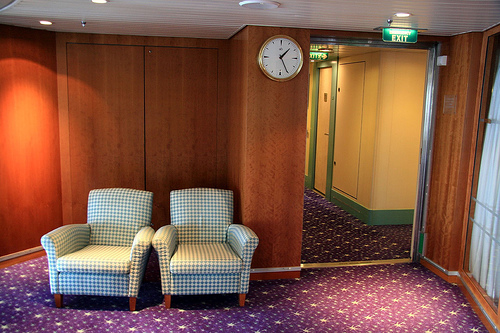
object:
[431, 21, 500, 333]
door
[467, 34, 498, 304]
glass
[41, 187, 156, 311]
chair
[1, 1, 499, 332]
room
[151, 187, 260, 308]
chair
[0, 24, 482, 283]
walls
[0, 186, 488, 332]
floor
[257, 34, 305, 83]
clock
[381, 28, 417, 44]
sign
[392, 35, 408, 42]
exit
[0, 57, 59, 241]
light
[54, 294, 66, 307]
legs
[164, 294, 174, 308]
legs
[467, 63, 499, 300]
curtain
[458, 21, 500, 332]
window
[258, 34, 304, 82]
trim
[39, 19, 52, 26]
light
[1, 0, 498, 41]
ceiling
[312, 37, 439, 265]
moulding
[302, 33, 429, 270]
doorway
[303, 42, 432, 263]
hall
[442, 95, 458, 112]
plate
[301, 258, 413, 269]
trim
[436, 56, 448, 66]
box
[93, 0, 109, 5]
light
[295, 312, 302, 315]
stars